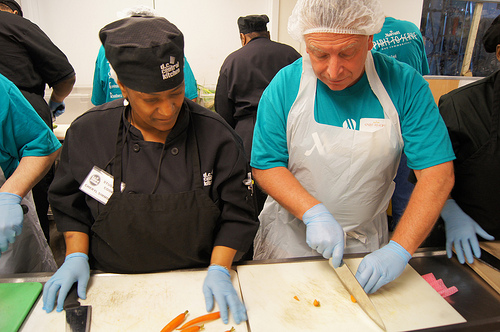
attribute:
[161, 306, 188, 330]
carrot slice — orange, thin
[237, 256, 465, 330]
carrot paper — white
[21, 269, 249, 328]
carrot paper — white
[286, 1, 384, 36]
hair net — white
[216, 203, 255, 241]
fabric — black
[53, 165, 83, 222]
fabric — black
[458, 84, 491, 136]
fabric — black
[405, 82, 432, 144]
fabric — black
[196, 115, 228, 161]
fabric — black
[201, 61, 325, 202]
shirt — black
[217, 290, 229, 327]
finger — blue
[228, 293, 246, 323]
finger — blue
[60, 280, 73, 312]
finger — blue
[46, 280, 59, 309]
finger — blue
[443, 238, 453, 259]
finger — blue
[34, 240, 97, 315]
blue glove — disposable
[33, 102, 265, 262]
shirt — black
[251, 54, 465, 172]
shirt — blue, white, short-sleeved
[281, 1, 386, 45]
cap — WHITE, PLASTIC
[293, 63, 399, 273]
apron — white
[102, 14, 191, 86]
chef hat — black, white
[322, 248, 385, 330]
chef's knife — large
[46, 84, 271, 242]
shirt — black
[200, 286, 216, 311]
finger — BLUE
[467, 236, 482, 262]
finger — blue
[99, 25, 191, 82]
hat — black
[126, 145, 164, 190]
fabric — black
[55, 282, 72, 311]
finger — BLUE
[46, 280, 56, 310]
finger — BLUE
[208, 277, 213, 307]
finger — BLUE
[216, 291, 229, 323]
finger — BLUE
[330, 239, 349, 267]
finger — BLUE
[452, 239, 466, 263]
finger — blue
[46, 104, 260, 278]
shirt — black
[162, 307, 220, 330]
carrots — long, orange